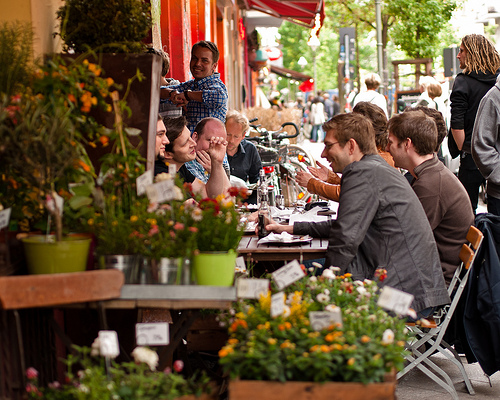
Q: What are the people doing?
A: Talking.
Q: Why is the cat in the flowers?
A: There is no cat.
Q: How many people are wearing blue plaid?
A: Two.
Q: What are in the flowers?
A: Tags.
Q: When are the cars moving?
A: There are no cars.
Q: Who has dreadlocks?
A: Man in black suit standing.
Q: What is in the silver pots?
A: Flowers.